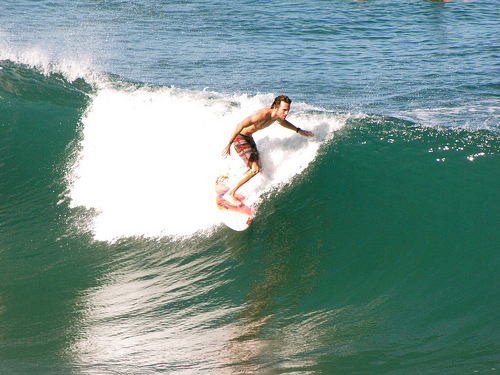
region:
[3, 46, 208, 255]
Wave formation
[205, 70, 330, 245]
Surfer riding a wave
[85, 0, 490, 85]
Mass of sea water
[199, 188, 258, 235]
Surfing board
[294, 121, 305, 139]
Watch worn by the surfer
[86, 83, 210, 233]
White color display of part of the wave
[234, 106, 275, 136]
Naked torso of the surfer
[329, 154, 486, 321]
Dark shade of color of water forming the wave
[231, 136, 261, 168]
Pair of shorts with red stripe along the side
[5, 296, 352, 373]
Gentle floor of the wave front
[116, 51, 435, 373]
a man is surfing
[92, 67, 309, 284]
a man is surfing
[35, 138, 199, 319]
bog splash of water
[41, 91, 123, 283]
bog splash of water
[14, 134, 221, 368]
bog splash of water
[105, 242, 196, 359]
bog splash of water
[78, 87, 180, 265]
bog splash of water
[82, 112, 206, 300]
bog splash of water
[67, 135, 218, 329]
bog splash of water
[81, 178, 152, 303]
bog splash of water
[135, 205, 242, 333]
bog splash of water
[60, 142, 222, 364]
bog splash of water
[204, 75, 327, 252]
a person swimming in water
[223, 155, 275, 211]
legs of the person in water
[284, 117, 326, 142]
hand of the person in water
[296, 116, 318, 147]
man touching the water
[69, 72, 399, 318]
a beautiful view of water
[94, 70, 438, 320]
a flow of water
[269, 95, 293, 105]
hairs of the person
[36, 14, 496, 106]
a calm set of water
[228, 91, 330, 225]
a person skatting in water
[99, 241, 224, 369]
shining of the water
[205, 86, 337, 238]
Man surfing in the ocean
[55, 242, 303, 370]
Reflection in the ocean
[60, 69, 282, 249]
Whitecap on top of the wave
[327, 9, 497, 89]
Still ocean in the background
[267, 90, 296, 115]
Man has brown hair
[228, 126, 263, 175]
Man is wearing bathing suit shorts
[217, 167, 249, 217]
The man is not wearing any shoes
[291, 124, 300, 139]
Man is wearing a watch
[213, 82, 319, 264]
Man is concentrating on surfing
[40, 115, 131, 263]
Water is splashing from the wave